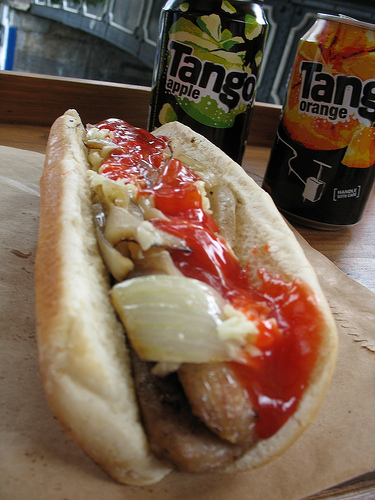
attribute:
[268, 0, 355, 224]
can — orange, soda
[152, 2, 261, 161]
can — apple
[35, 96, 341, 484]
bun — open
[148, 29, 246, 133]
colors — green, black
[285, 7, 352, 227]
can — orange, Black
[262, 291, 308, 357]
sauce — tomato 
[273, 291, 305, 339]
sauce — tomato  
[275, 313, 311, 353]
sauce — tomato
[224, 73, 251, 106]
letter — black 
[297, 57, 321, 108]
letter — black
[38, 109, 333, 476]
dog — large, sausage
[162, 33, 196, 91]
letter — black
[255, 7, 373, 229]
can — Orange Tango